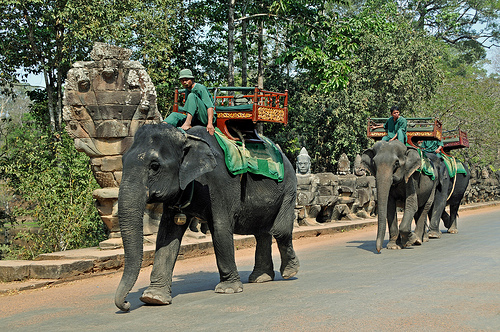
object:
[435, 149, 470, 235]
elephant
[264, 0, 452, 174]
trees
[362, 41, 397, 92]
leaves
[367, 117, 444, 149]
wooden cart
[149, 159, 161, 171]
eye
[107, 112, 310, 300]
elephant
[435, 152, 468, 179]
green blanket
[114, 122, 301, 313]
elephant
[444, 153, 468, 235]
elephant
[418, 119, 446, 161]
man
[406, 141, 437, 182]
blanket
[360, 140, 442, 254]
elephant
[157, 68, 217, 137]
driver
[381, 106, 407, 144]
driver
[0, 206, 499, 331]
ground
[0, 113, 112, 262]
trees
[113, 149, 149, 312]
trunk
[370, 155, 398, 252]
trunk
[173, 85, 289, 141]
cart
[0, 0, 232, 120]
trees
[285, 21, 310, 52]
leaves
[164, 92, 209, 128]
green pants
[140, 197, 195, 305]
leg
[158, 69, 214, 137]
man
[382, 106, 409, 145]
man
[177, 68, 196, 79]
hat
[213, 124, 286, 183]
blanket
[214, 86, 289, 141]
back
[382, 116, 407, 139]
shirt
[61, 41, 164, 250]
statue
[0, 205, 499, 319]
dirt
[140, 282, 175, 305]
foot